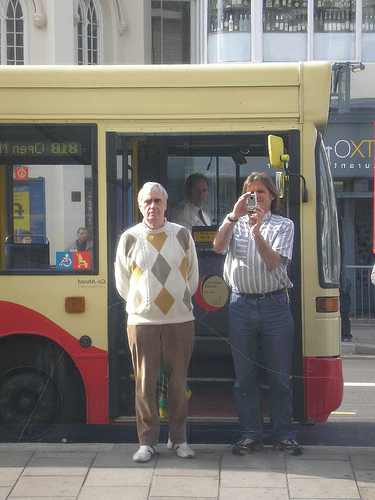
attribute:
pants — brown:
[125, 318, 194, 443]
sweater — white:
[114, 218, 199, 323]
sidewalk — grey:
[1, 442, 373, 498]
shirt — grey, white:
[218, 207, 295, 297]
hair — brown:
[239, 167, 282, 199]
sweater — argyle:
[109, 219, 207, 320]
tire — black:
[2, 334, 108, 455]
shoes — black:
[235, 433, 305, 461]